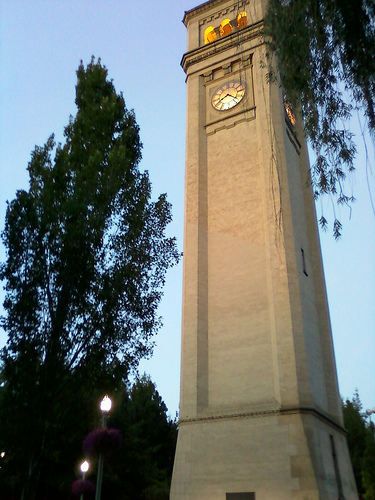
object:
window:
[200, 11, 246, 44]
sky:
[1, 1, 375, 423]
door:
[329, 433, 345, 500]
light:
[201, 10, 245, 45]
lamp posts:
[95, 411, 111, 497]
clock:
[210, 81, 247, 113]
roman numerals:
[233, 87, 243, 103]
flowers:
[84, 425, 123, 454]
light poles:
[93, 410, 115, 500]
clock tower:
[169, 0, 359, 500]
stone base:
[168, 416, 362, 499]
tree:
[0, 52, 183, 500]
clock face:
[282, 100, 297, 128]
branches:
[309, 79, 374, 243]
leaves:
[333, 219, 343, 240]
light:
[203, 23, 213, 45]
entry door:
[326, 434, 347, 498]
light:
[99, 395, 114, 415]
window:
[298, 247, 308, 274]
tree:
[275, 0, 375, 242]